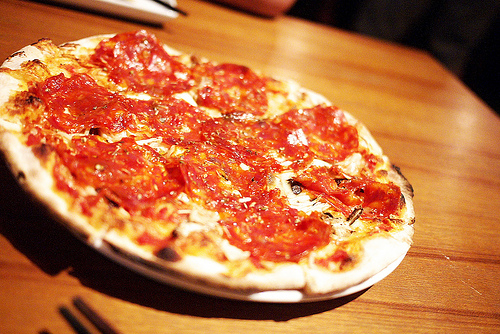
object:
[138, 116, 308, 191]
pepperoni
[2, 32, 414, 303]
plate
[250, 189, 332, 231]
cheese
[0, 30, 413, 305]
pizza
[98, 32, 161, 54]
elbow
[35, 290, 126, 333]
silverware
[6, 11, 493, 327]
table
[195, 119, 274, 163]
pepporini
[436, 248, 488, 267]
dark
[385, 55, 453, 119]
shine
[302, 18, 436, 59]
edge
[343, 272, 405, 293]
edge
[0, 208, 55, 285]
shadow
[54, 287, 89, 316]
edge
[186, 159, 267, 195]
small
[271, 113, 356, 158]
piece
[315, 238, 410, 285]
part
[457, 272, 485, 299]
scratch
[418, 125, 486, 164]
wood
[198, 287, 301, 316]
dish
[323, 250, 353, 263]
tomato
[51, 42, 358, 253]
top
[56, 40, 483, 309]
pizza place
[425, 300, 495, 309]
lines